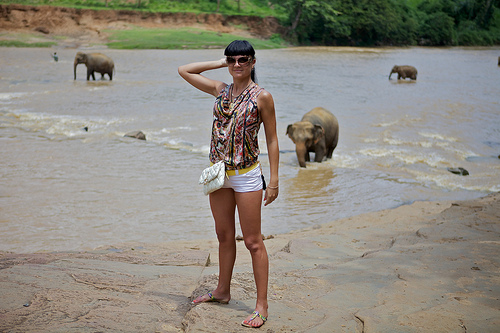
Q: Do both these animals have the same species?
A: Yes, all the animals are elephants.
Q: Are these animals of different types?
A: No, all the animals are elephants.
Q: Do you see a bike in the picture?
A: No, there are no bikes.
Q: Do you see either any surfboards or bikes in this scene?
A: No, there are no bikes or surfboards.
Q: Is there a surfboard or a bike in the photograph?
A: No, there are no bikes or surfboards.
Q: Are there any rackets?
A: No, there are no rackets.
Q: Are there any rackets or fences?
A: No, there are no rackets or fences.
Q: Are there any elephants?
A: Yes, there is an elephant.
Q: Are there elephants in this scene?
A: Yes, there is an elephant.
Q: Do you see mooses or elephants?
A: Yes, there is an elephant.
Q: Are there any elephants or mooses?
A: Yes, there is an elephant.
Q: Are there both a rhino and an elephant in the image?
A: No, there is an elephant but no rhinos.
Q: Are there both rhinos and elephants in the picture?
A: No, there is an elephant but no rhinos.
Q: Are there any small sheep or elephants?
A: Yes, there is a small elephant.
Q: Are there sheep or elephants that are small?
A: Yes, the elephant is small.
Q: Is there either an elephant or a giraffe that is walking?
A: Yes, the elephant is walking.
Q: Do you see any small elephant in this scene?
A: Yes, there is a small elephant.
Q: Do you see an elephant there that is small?
A: Yes, there is an elephant that is small.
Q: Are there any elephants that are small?
A: Yes, there is an elephant that is small.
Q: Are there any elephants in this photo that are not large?
A: Yes, there is a small elephant.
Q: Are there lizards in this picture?
A: No, there are no lizards.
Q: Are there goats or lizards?
A: No, there are no lizards or goats.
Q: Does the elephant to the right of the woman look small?
A: Yes, the elephant is small.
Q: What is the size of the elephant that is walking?
A: The elephant is small.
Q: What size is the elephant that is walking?
A: The elephant is small.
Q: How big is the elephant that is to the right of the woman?
A: The elephant is small.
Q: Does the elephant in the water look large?
A: No, the elephant is small.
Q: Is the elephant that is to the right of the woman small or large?
A: The elephant is small.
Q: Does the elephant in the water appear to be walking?
A: Yes, the elephant is walking.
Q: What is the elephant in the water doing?
A: The elephant is walking.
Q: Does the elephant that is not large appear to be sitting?
A: No, the elephant is walking.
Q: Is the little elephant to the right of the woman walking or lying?
A: The elephant is walking.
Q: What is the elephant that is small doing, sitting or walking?
A: The elephant is walking.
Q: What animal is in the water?
A: The elephant is in the water.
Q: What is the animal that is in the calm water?
A: The animal is an elephant.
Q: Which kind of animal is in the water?
A: The animal is an elephant.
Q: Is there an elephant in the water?
A: Yes, there is an elephant in the water.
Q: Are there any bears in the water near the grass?
A: No, there is an elephant in the water.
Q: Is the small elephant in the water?
A: Yes, the elephant is in the water.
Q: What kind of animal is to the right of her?
A: The animal is an elephant.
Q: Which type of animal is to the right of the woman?
A: The animal is an elephant.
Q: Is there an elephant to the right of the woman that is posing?
A: Yes, there is an elephant to the right of the woman.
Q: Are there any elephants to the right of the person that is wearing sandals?
A: Yes, there is an elephant to the right of the woman.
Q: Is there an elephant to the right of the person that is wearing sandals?
A: Yes, there is an elephant to the right of the woman.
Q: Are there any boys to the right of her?
A: No, there is an elephant to the right of the woman.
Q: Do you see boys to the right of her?
A: No, there is an elephant to the right of the woman.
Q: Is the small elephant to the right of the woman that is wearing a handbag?
A: Yes, the elephant is to the right of the woman.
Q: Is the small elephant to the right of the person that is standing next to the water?
A: Yes, the elephant is to the right of the woman.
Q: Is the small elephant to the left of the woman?
A: No, the elephant is to the right of the woman.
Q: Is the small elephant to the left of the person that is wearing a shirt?
A: No, the elephant is to the right of the woman.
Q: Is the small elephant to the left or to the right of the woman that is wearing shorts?
A: The elephant is to the right of the woman.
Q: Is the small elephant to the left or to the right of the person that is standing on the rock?
A: The elephant is to the right of the woman.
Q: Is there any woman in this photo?
A: Yes, there is a woman.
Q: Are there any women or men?
A: Yes, there is a woman.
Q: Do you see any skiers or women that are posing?
A: Yes, the woman is posing.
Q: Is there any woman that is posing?
A: Yes, there is a woman that is posing.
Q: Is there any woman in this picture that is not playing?
A: Yes, there is a woman that is posing.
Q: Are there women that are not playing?
A: Yes, there is a woman that is posing.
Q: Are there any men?
A: No, there are no men.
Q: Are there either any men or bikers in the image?
A: No, there are no men or bikers.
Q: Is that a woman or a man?
A: That is a woman.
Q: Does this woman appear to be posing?
A: Yes, the woman is posing.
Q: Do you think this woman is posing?
A: Yes, the woman is posing.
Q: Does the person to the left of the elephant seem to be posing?
A: Yes, the woman is posing.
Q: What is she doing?
A: The woman is posing.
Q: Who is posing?
A: The woman is posing.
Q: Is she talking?
A: No, the woman is posing.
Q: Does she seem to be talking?
A: No, the woman is posing.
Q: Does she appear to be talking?
A: No, the woman is posing.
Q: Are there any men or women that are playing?
A: No, there is a woman but she is posing.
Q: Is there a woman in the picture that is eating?
A: No, there is a woman but she is posing.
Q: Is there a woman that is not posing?
A: No, there is a woman but she is posing.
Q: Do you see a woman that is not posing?
A: No, there is a woman but she is posing.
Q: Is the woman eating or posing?
A: The woman is posing.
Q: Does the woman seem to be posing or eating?
A: The woman is posing.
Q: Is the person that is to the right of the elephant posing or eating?
A: The woman is posing.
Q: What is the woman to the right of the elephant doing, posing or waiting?
A: The woman is posing.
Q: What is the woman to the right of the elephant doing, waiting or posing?
A: The woman is posing.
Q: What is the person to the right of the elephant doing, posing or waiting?
A: The woman is posing.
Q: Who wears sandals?
A: The woman wears sandals.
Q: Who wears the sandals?
A: The woman wears sandals.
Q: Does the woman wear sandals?
A: Yes, the woman wears sandals.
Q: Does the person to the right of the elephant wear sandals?
A: Yes, the woman wears sandals.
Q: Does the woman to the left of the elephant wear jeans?
A: No, the woman wears sandals.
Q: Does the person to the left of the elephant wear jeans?
A: No, the woman wears sandals.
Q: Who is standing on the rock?
A: The woman is standing on the rock.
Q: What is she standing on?
A: The woman is standing on the rock.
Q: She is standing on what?
A: The woman is standing on the rock.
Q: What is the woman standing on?
A: The woman is standing on the rock.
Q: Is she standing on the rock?
A: Yes, the woman is standing on the rock.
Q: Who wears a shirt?
A: The woman wears a shirt.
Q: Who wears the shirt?
A: The woman wears a shirt.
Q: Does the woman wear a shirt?
A: Yes, the woman wears a shirt.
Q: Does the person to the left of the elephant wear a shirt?
A: Yes, the woman wears a shirt.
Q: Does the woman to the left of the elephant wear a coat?
A: No, the woman wears a shirt.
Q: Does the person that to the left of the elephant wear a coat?
A: No, the woman wears a shirt.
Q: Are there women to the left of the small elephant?
A: Yes, there is a woman to the left of the elephant.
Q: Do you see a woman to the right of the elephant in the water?
A: No, the woman is to the left of the elephant.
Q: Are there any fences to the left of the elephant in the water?
A: No, there is a woman to the left of the elephant.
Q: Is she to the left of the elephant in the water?
A: Yes, the woman is to the left of the elephant.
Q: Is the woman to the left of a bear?
A: No, the woman is to the left of the elephant.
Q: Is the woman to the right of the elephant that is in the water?
A: No, the woman is to the left of the elephant.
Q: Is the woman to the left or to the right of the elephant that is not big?
A: The woman is to the left of the elephant.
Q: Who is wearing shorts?
A: The woman is wearing shorts.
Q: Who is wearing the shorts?
A: The woman is wearing shorts.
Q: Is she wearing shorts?
A: Yes, the woman is wearing shorts.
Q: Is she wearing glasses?
A: No, the woman is wearing shorts.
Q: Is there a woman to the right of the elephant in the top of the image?
A: Yes, there is a woman to the right of the elephant.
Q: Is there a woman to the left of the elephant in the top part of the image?
A: No, the woman is to the right of the elephant.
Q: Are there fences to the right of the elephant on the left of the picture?
A: No, there is a woman to the right of the elephant.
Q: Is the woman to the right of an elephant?
A: Yes, the woman is to the right of an elephant.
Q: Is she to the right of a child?
A: No, the woman is to the right of an elephant.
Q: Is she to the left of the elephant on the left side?
A: No, the woman is to the right of the elephant.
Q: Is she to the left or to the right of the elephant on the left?
A: The woman is to the right of the elephant.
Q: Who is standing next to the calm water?
A: The woman is standing next to the water.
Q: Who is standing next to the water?
A: The woman is standing next to the water.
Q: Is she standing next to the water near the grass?
A: Yes, the woman is standing next to the water.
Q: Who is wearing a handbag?
A: The woman is wearing a handbag.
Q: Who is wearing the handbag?
A: The woman is wearing a handbag.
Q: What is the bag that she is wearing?
A: The bag is a handbag.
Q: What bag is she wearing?
A: The woman is wearing a handbag.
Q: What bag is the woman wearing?
A: The woman is wearing a handbag.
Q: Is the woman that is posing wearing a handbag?
A: Yes, the woman is wearing a handbag.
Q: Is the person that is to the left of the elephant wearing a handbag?
A: Yes, the woman is wearing a handbag.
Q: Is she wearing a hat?
A: No, the woman is wearing a handbag.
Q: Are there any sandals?
A: Yes, there are sandals.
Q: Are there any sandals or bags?
A: Yes, there are sandals.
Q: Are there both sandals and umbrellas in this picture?
A: No, there are sandals but no umbrellas.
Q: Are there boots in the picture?
A: No, there are no boots.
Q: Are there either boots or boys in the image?
A: No, there are no boots or boys.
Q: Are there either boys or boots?
A: No, there are no boots or boys.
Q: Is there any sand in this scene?
A: Yes, there is sand.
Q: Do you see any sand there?
A: Yes, there is sand.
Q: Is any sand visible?
A: Yes, there is sand.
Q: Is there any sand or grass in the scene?
A: Yes, there is sand.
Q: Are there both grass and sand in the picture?
A: Yes, there are both sand and grass.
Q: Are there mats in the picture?
A: No, there are no mats.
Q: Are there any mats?
A: No, there are no mats.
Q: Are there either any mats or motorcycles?
A: No, there are no mats or motorcycles.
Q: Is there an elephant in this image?
A: Yes, there is an elephant.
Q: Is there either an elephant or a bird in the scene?
A: Yes, there is an elephant.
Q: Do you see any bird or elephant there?
A: Yes, there is an elephant.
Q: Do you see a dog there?
A: No, there are no dogs.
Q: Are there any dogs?
A: No, there are no dogs.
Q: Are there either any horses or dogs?
A: No, there are no dogs or horses.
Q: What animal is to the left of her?
A: The animal is an elephant.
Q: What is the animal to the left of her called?
A: The animal is an elephant.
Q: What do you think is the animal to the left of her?
A: The animal is an elephant.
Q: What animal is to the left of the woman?
A: The animal is an elephant.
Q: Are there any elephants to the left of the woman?
A: Yes, there is an elephant to the left of the woman.